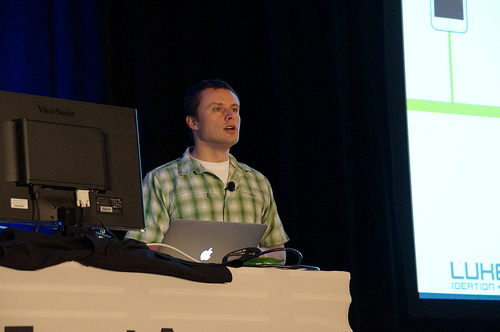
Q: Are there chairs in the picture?
A: No, there are no chairs.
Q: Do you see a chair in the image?
A: No, there are no chairs.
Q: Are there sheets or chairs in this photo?
A: No, there are no chairs or sheets.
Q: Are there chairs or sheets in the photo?
A: No, there are no chairs or sheets.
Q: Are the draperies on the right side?
A: No, the draperies are on the left of the image.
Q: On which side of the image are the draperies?
A: The draperies are on the left of the image.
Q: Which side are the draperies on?
A: The draperies are on the left of the image.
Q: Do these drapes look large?
A: Yes, the drapes are large.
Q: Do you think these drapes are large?
A: Yes, the drapes are large.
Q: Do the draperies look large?
A: Yes, the draperies are large.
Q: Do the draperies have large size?
A: Yes, the draperies are large.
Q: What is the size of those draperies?
A: The draperies are large.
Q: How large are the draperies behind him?
A: The drapes are large.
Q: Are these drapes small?
A: No, the drapes are large.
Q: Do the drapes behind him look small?
A: No, the draperies are large.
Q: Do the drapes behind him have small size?
A: No, the draperies are large.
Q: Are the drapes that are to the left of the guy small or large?
A: The draperies are large.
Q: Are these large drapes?
A: Yes, these are large drapes.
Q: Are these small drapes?
A: No, these are large drapes.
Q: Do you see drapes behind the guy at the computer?
A: Yes, there are drapes behind the guy.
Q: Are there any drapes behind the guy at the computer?
A: Yes, there are drapes behind the guy.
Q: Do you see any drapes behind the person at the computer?
A: Yes, there are drapes behind the guy.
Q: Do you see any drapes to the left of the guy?
A: Yes, there are drapes to the left of the guy.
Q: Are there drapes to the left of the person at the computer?
A: Yes, there are drapes to the left of the guy.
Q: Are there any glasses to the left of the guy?
A: No, there are drapes to the left of the guy.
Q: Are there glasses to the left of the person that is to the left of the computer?
A: No, there are drapes to the left of the guy.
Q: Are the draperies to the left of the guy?
A: Yes, the draperies are to the left of the guy.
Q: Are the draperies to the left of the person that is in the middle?
A: Yes, the draperies are to the left of the guy.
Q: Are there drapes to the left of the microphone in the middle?
A: Yes, there are drapes to the left of the microphone.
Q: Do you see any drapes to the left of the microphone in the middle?
A: Yes, there are drapes to the left of the microphone.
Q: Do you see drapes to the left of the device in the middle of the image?
A: Yes, there are drapes to the left of the microphone.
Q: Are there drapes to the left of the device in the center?
A: Yes, there are drapes to the left of the microphone.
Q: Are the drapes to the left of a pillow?
A: No, the drapes are to the left of the microphone.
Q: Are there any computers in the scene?
A: Yes, there is a computer.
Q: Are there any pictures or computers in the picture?
A: Yes, there is a computer.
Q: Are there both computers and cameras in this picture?
A: No, there is a computer but no cameras.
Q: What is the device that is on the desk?
A: The device is a computer.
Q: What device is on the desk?
A: The device is a computer.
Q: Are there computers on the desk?
A: Yes, there is a computer on the desk.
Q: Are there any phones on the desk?
A: No, there is a computer on the desk.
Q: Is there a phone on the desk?
A: No, there is a computer on the desk.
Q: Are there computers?
A: Yes, there is a computer.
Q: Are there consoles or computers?
A: Yes, there is a computer.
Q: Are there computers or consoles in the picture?
A: Yes, there is a computer.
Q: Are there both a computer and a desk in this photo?
A: Yes, there are both a computer and a desk.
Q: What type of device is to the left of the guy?
A: The device is a computer.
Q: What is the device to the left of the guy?
A: The device is a computer.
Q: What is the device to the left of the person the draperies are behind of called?
A: The device is a computer.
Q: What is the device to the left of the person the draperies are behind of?
A: The device is a computer.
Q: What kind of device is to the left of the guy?
A: The device is a computer.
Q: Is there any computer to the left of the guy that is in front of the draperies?
A: Yes, there is a computer to the left of the guy.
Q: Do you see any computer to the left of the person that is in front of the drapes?
A: Yes, there is a computer to the left of the guy.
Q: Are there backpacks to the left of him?
A: No, there is a computer to the left of the guy.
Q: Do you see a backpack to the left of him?
A: No, there is a computer to the left of the guy.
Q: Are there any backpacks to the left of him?
A: No, there is a computer to the left of the guy.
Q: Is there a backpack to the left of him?
A: No, there is a computer to the left of the guy.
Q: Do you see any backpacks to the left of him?
A: No, there is a computer to the left of the guy.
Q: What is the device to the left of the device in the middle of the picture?
A: The device is a computer.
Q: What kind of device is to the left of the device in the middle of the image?
A: The device is a computer.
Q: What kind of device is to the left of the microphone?
A: The device is a computer.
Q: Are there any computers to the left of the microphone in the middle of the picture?
A: Yes, there is a computer to the left of the microphone.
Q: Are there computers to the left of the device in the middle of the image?
A: Yes, there is a computer to the left of the microphone.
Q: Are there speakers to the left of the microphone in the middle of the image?
A: No, there is a computer to the left of the microphone.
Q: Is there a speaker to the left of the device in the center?
A: No, there is a computer to the left of the microphone.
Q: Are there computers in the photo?
A: Yes, there is a computer.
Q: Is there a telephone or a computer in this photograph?
A: Yes, there is a computer.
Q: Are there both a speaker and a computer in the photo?
A: No, there is a computer but no speakers.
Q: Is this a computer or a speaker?
A: This is a computer.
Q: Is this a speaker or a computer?
A: This is a computer.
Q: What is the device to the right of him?
A: The device is a computer.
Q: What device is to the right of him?
A: The device is a computer.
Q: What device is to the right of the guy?
A: The device is a computer.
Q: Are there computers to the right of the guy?
A: Yes, there is a computer to the right of the guy.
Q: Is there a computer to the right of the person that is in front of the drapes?
A: Yes, there is a computer to the right of the guy.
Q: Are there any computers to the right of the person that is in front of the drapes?
A: Yes, there is a computer to the right of the guy.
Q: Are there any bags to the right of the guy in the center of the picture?
A: No, there is a computer to the right of the guy.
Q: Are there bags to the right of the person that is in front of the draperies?
A: No, there is a computer to the right of the guy.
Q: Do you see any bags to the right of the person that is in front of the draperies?
A: No, there is a computer to the right of the guy.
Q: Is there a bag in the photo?
A: No, there are no bags.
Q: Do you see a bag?
A: No, there are no bags.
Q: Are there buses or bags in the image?
A: No, there are no bags or buses.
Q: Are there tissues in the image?
A: No, there are no tissues.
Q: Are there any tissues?
A: No, there are no tissues.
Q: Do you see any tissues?
A: No, there are no tissues.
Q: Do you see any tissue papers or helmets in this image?
A: No, there are no tissue papers or helmets.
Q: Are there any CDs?
A: No, there are no cds.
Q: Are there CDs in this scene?
A: No, there are no cds.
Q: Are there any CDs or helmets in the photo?
A: No, there are no CDs or helmets.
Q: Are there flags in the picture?
A: No, there are no flags.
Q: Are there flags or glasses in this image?
A: No, there are no flags or glasses.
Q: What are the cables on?
A: The cables are on the desk.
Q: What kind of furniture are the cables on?
A: The cables are on the desk.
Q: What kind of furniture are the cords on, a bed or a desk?
A: The cords are on a desk.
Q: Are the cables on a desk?
A: Yes, the cables are on a desk.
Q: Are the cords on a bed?
A: No, the cords are on a desk.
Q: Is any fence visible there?
A: No, there are no fences.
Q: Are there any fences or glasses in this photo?
A: No, there are no fences or glasses.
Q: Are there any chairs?
A: No, there are no chairs.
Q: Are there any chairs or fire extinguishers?
A: No, there are no chairs or fire extinguishers.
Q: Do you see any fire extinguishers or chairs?
A: No, there are no chairs or fire extinguishers.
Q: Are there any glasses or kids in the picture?
A: No, there are no glasses or kids.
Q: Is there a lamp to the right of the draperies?
A: No, there is a guy to the right of the draperies.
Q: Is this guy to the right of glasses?
A: No, the guy is to the right of the draperies.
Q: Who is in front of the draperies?
A: The guy is in front of the draperies.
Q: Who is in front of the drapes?
A: The guy is in front of the draperies.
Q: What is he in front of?
A: The guy is in front of the draperies.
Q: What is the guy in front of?
A: The guy is in front of the draperies.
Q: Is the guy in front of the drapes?
A: Yes, the guy is in front of the drapes.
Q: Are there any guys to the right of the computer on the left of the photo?
A: Yes, there is a guy to the right of the computer.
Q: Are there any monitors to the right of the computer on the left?
A: No, there is a guy to the right of the computer.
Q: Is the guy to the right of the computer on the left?
A: Yes, the guy is to the right of the computer.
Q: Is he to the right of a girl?
A: No, the guy is to the right of the computer.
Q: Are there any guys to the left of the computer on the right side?
A: Yes, there is a guy to the left of the computer.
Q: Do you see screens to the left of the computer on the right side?
A: No, there is a guy to the left of the computer.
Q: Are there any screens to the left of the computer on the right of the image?
A: No, there is a guy to the left of the computer.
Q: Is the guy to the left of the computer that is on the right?
A: Yes, the guy is to the left of the computer.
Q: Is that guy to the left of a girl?
A: No, the guy is to the left of the computer.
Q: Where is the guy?
A: The guy is at the computer.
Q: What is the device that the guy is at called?
A: The device is a computer.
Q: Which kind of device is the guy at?
A: The guy is at the computer.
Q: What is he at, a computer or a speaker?
A: The guy is at a computer.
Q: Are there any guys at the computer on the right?
A: Yes, there is a guy at the computer.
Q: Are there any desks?
A: Yes, there is a desk.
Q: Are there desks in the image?
A: Yes, there is a desk.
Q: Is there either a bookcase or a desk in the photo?
A: Yes, there is a desk.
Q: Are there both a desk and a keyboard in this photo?
A: No, there is a desk but no keyboards.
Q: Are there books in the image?
A: No, there are no books.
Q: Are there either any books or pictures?
A: No, there are no books or pictures.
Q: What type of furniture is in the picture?
A: The furniture is a desk.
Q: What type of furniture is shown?
A: The furniture is a desk.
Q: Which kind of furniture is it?
A: The piece of furniture is a desk.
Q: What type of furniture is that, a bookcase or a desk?
A: This is a desk.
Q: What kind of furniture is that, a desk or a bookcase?
A: This is a desk.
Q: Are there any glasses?
A: No, there are no glasses.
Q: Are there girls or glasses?
A: No, there are no glasses or girls.